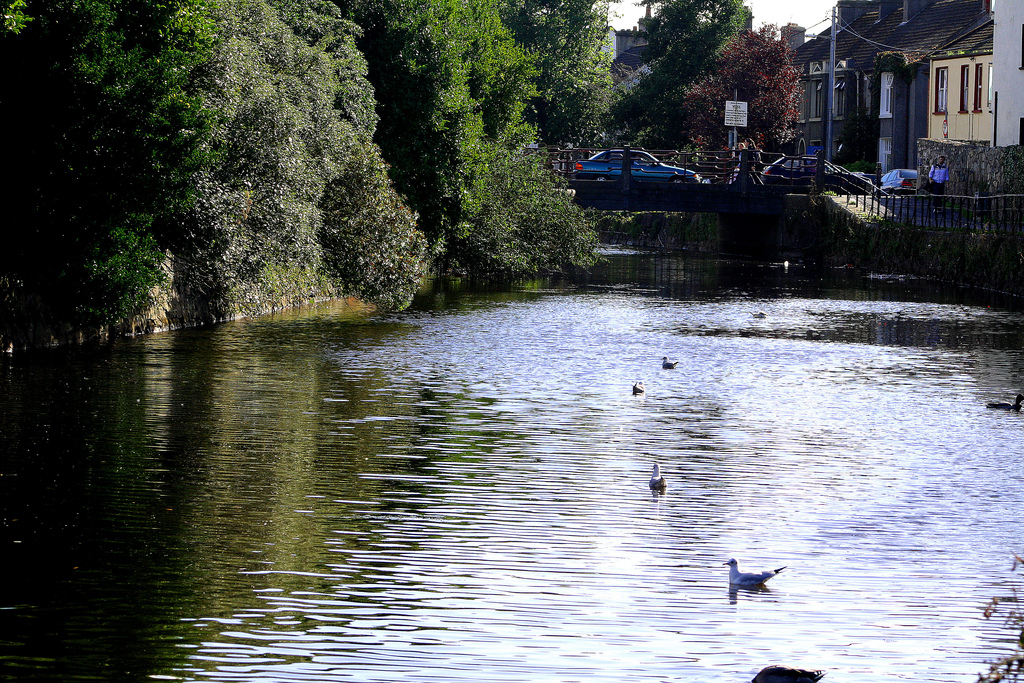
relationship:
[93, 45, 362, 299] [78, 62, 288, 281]
leaves on tree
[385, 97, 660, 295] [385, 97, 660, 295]
leaves on tree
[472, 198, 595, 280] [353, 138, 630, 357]
leaves on tree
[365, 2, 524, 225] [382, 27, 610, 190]
leaves on tree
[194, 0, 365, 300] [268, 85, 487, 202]
leaves on tree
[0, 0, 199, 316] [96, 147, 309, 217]
leaves on tree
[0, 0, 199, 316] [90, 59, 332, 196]
leaves on tree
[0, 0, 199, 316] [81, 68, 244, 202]
leaves on tree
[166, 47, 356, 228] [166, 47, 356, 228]
leaves on tree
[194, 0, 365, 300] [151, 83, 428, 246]
leaves on tree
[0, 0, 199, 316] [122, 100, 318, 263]
leaves on tree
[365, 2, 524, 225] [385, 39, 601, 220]
leaves on tree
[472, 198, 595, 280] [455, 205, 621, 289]
leaves on tree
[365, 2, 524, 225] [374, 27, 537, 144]
leaves on tree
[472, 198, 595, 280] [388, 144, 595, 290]
leaves on tree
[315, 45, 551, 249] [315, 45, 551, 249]
leaves on tree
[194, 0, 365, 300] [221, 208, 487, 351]
leaves on tree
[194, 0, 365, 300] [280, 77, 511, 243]
leaves on tree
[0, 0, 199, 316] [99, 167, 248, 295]
leaves on tree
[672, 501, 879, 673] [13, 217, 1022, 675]
bird in water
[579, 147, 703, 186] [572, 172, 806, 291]
car on a bridge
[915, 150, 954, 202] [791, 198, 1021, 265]
man walking on sidewalk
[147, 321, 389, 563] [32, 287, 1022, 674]
reflection in water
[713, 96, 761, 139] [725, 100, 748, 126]
sign mounted on sign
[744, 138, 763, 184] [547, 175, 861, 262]
person walking on bridge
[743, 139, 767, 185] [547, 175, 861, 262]
person walking on bridge